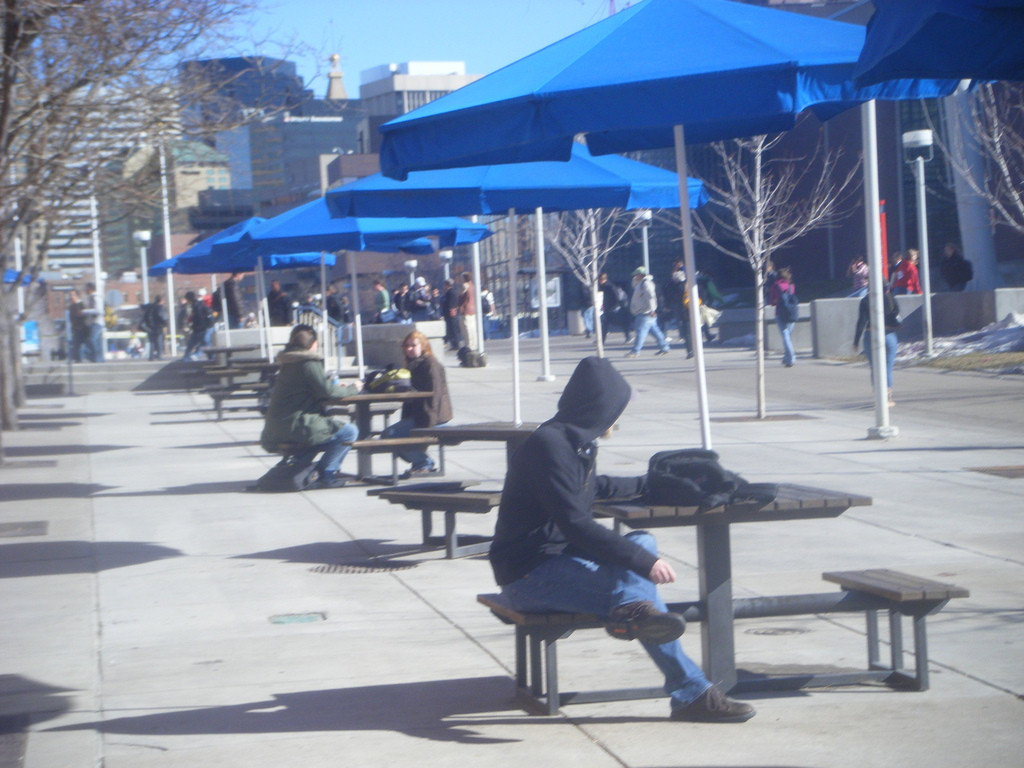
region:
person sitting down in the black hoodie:
[492, 332, 749, 724]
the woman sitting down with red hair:
[383, 325, 470, 472]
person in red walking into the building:
[886, 227, 929, 313]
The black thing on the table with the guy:
[650, 440, 772, 507]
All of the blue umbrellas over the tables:
[125, 6, 1021, 298]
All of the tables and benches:
[153, 304, 947, 729]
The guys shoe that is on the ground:
[680, 674, 785, 732]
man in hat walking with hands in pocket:
[619, 259, 673, 362]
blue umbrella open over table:
[321, 111, 714, 432]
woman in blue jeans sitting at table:
[251, 320, 362, 499]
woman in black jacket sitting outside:
[368, 325, 455, 488]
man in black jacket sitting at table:
[485, 348, 758, 737]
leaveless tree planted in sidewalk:
[644, 118, 867, 426]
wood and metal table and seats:
[464, 471, 976, 724]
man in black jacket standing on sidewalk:
[259, 270, 299, 332]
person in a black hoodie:
[496, 351, 760, 729]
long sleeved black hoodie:
[468, 350, 659, 598]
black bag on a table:
[634, 439, 791, 519]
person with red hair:
[381, 325, 462, 484]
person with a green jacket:
[245, 320, 366, 491]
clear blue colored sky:
[29, 2, 659, 114]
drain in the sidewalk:
[266, 604, 336, 631]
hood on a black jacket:
[555, 356, 633, 437]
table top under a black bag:
[584, 476, 880, 524]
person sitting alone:
[487, 347, 763, 736]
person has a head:
[286, 318, 318, 350]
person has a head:
[561, 357, 628, 438]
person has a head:
[397, 328, 432, 357]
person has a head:
[778, 271, 794, 287]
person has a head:
[634, 263, 647, 274]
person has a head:
[852, 256, 868, 282]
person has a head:
[905, 247, 921, 264]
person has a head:
[940, 244, 951, 263]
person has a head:
[459, 275, 478, 294]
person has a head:
[371, 277, 384, 291]